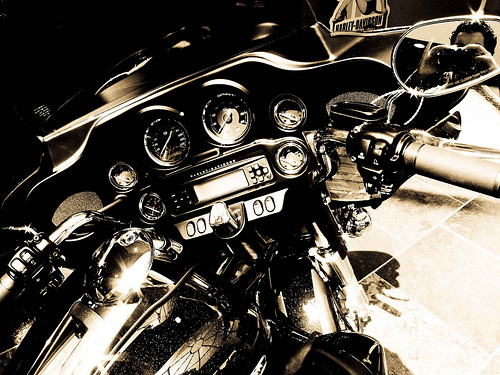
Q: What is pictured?
A: A motorcycle.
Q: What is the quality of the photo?
A: Clear black and white.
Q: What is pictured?
A: The control panel of motorcycle.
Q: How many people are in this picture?
A: One.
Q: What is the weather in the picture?
A: Sunny and bright.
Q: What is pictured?
A: The gauges of a motorcycle.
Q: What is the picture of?
A: A motorcycle.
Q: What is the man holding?
A: A camera.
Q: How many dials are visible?
A: 6.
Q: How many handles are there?
A: 2.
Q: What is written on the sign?
A: Harley-Davidson.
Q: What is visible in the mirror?
A: A man.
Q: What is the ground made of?
A: Tiles.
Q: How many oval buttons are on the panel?
A: 4.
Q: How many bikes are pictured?
A: One.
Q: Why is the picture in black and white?
A: Sepia color.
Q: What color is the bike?
A: Black.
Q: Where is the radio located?
A: The middle.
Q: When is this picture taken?
A: While parked.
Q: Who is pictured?
A: No one.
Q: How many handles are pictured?
A: Two.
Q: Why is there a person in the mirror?
A: Reflection.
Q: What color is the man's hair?
A: Black.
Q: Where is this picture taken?
A: Up above.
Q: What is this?
A: A motorcycle.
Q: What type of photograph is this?
A: Black & white.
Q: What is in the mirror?
A: A man.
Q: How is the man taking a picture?
A: In the mirror.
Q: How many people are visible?
A: 1.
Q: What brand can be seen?
A: Harley Davidson.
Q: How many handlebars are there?
A: 2.